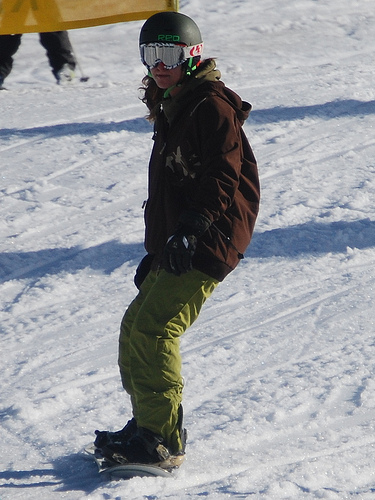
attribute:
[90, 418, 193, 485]
mesh sled — yellow, snow, for snowboard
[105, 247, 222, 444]
snow pants — olive green, impermeable, wrinkled, green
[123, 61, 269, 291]
jacket — brown, hooded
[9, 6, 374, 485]
snow — white, snowy, sparkling packed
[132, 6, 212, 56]
helmet — black, green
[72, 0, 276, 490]
female — snowboarding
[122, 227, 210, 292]
gloves — black, white, sliver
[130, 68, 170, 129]
hair — curly, brown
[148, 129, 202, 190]
jacket front — decorate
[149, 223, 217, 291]
glove — black